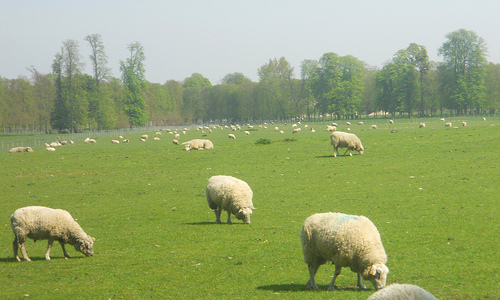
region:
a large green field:
[0, 25, 496, 298]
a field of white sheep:
[0, 108, 491, 298]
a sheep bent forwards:
[202, 172, 261, 229]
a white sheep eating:
[202, 168, 258, 226]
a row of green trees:
[3, 27, 497, 141]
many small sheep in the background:
[6, 111, 491, 161]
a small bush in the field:
[250, 136, 295, 147]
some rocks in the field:
[179, 135, 214, 155]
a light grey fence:
[0, 117, 270, 154]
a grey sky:
[1, 1, 498, 84]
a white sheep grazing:
[8, 204, 96, 261]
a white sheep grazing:
[204, 172, 256, 227]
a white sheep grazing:
[298, 209, 389, 291]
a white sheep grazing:
[326, 128, 364, 157]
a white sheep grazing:
[181, 138, 213, 150]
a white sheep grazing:
[226, 130, 236, 140]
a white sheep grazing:
[171, 137, 179, 145]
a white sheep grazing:
[8, 143, 29, 153]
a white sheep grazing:
[46, 145, 53, 151]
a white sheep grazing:
[416, 120, 427, 127]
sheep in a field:
[18, 54, 493, 291]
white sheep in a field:
[26, 89, 343, 296]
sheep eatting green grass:
[39, 56, 489, 278]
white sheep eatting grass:
[15, 115, 450, 299]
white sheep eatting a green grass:
[26, 93, 482, 298]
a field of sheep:
[22, 88, 499, 285]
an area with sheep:
[47, 71, 496, 281]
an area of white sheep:
[18, 78, 428, 295]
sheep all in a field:
[30, 73, 499, 290]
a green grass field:
[51, 73, 494, 294]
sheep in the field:
[8, 206, 94, 260]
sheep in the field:
[206, 175, 253, 225]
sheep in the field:
[305, 212, 385, 289]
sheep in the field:
[330, 132, 364, 157]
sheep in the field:
[183, 140, 215, 151]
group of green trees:
[48, 40, 148, 130]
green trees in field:
[437, 39, 485, 109]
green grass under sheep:
[11, 120, 491, 297]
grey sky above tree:
[4, 3, 498, 82]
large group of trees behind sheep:
[2, 65, 494, 127]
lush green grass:
[388, 148, 495, 255]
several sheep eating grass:
[163, 127, 444, 292]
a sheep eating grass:
[8, 198, 105, 275]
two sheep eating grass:
[4, 160, 262, 295]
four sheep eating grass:
[6, 123, 401, 297]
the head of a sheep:
[76, 233, 96, 258]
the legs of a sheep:
[7, 238, 72, 268]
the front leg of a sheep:
[58, 241, 70, 258]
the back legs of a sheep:
[11, 235, 35, 261]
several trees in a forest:
[6, 28, 499, 106]